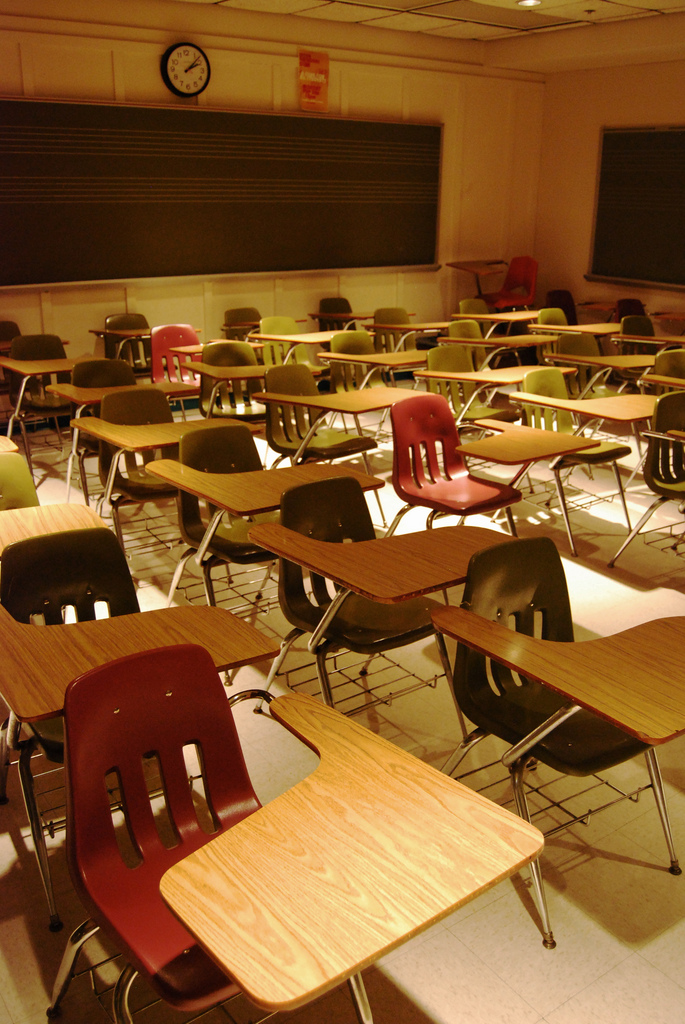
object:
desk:
[248, 528, 517, 611]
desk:
[139, 441, 382, 515]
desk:
[69, 416, 263, 454]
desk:
[249, 384, 437, 412]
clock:
[160, 41, 212, 98]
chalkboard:
[0, 95, 442, 287]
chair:
[381, 392, 521, 539]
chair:
[261, 361, 381, 470]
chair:
[256, 477, 478, 746]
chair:
[438, 534, 685, 950]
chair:
[164, 424, 283, 684]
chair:
[198, 339, 284, 419]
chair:
[491, 362, 632, 554]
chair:
[426, 345, 524, 425]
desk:
[453, 425, 602, 464]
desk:
[247, 329, 376, 345]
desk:
[44, 375, 202, 407]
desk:
[507, 391, 670, 423]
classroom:
[0, 0, 685, 1024]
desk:
[429, 611, 684, 742]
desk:
[317, 347, 449, 371]